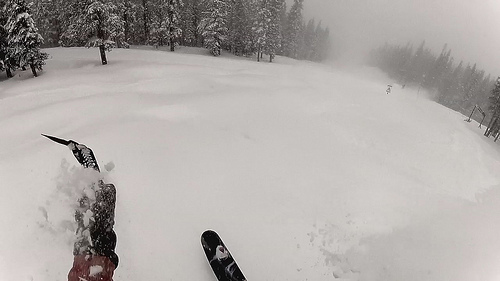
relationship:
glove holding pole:
[44, 178, 137, 255] [34, 120, 121, 221]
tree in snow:
[82, 7, 117, 47] [241, 122, 326, 180]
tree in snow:
[4, 5, 50, 77] [53, 88, 193, 161]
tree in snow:
[83, 1, 125, 66] [7, 0, 498, 274]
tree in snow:
[83, 1, 125, 66] [0, 27, 495, 279]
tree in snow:
[156, 2, 185, 54] [0, 27, 495, 279]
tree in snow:
[194, 1, 232, 54] [0, 27, 495, 279]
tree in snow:
[247, 1, 283, 61] [0, 27, 495, 279]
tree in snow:
[4, 1, 47, 75] [0, 27, 495, 279]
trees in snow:
[364, 9, 498, 121] [358, 79, 437, 201]